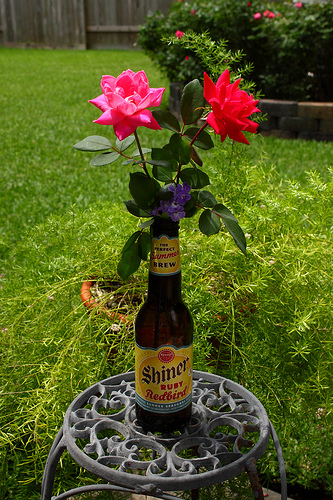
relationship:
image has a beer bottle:
[1, 5, 330, 493] [120, 222, 200, 433]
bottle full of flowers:
[120, 222, 200, 433] [92, 56, 269, 165]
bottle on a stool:
[120, 222, 200, 433] [30, 365, 287, 499]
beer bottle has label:
[120, 222, 200, 433] [133, 332, 193, 417]